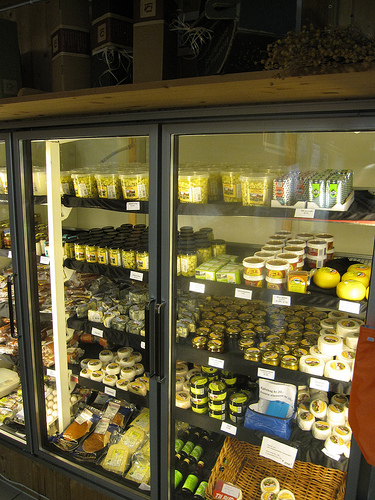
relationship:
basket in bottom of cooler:
[212, 436, 348, 498] [4, 110, 374, 495]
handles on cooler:
[139, 296, 168, 388] [4, 110, 374, 495]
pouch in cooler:
[246, 401, 291, 442] [4, 110, 374, 495]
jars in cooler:
[193, 288, 334, 368] [4, 110, 374, 495]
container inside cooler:
[248, 227, 326, 292] [4, 110, 374, 495]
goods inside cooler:
[302, 310, 361, 388] [4, 110, 374, 495]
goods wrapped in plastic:
[302, 310, 361, 388] [325, 334, 335, 352]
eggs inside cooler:
[20, 384, 79, 432] [4, 110, 374, 495]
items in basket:
[260, 475, 294, 500] [212, 436, 348, 498]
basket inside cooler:
[212, 436, 348, 498] [4, 110, 374, 495]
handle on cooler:
[6, 273, 24, 340] [4, 110, 374, 495]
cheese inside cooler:
[325, 251, 372, 309] [4, 110, 374, 495]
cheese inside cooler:
[80, 340, 151, 394] [4, 110, 374, 495]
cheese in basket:
[260, 475, 294, 500] [212, 436, 348, 498]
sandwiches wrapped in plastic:
[67, 400, 119, 462] [325, 334, 335, 352]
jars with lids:
[189, 360, 247, 424] [189, 374, 225, 389]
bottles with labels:
[159, 423, 215, 499] [181, 476, 212, 497]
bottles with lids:
[159, 423, 215, 499] [178, 454, 210, 465]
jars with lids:
[193, 288, 334, 368] [224, 305, 314, 361]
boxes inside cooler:
[304, 164, 349, 211] [4, 110, 374, 495]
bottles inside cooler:
[69, 218, 222, 276] [4, 110, 374, 495]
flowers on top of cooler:
[258, 24, 374, 78] [4, 110, 374, 495]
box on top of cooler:
[52, 48, 92, 92] [4, 110, 374, 495]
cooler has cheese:
[4, 110, 374, 495] [325, 251, 372, 309]